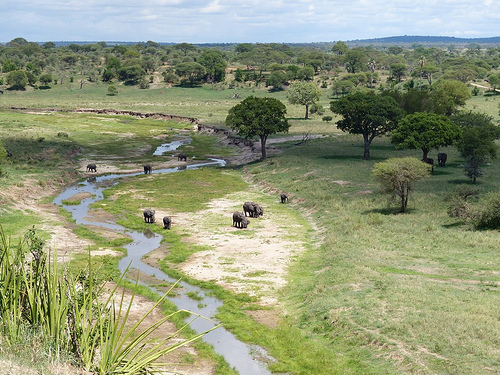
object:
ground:
[3, 88, 499, 374]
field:
[0, 55, 500, 375]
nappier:
[0, 107, 406, 375]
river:
[51, 136, 279, 375]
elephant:
[143, 208, 155, 223]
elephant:
[281, 193, 289, 203]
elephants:
[233, 201, 264, 228]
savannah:
[0, 38, 500, 375]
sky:
[2, 0, 500, 43]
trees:
[327, 78, 499, 213]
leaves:
[0, 224, 223, 375]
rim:
[1, 165, 78, 214]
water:
[52, 173, 107, 208]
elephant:
[437, 152, 447, 167]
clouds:
[0, 0, 500, 44]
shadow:
[361, 207, 415, 216]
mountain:
[349, 35, 499, 46]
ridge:
[1, 168, 59, 227]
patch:
[139, 190, 319, 328]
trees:
[225, 94, 290, 158]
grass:
[0, 86, 499, 375]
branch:
[294, 130, 312, 146]